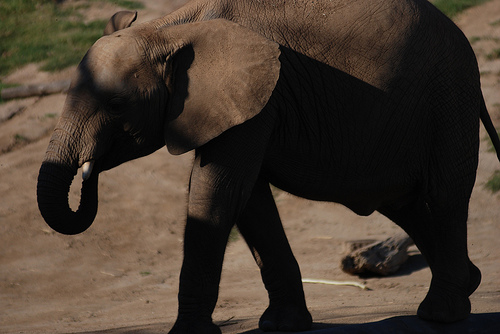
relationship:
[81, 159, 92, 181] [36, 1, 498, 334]
tusk on elephant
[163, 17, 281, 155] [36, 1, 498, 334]
ear on elephant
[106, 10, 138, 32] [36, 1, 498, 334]
ear on elephant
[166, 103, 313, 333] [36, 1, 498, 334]
legs of elephant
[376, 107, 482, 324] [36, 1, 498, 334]
legs of elephant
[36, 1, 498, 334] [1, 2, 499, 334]
elephant on ground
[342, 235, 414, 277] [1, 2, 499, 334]
rock on ground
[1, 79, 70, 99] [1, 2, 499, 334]
trunk on ground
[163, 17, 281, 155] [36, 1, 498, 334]
ear of elephant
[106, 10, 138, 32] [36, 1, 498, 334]
ear of elephant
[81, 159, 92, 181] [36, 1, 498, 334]
tusk of elephant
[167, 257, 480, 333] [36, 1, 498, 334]
feet of elephant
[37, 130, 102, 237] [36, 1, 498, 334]
trunk of elephant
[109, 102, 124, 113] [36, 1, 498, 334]
eye of elephant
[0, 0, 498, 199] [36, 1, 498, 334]
grass behind elephant